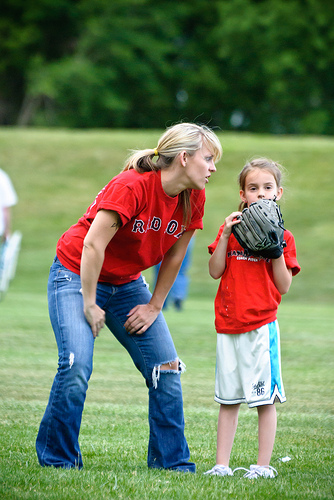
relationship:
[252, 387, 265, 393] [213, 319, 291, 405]
number on short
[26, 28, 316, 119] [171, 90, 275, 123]
branches in shade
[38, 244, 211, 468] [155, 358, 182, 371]
pants with tear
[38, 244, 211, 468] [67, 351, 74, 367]
pants with tear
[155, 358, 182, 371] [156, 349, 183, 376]
tear at knee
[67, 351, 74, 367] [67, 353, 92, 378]
tear at knee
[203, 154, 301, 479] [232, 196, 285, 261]
girl with glove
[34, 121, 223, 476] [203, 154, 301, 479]
woman giving advice to girl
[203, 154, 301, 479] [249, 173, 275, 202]
girl with look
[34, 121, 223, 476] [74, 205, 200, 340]
woman resting arms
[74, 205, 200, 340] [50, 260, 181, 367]
arms on thighs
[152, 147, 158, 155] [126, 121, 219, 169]
hairband in hair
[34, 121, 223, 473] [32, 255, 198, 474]
woman wearing pants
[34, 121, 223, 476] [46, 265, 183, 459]
woman wearing pants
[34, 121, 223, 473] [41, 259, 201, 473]
woman wearing jeans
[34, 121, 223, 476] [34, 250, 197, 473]
woman wearing pants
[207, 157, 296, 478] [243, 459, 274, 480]
girl wearing shoe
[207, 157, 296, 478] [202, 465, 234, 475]
girl wearing tennis shoe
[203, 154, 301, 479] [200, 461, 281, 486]
girl wearing shoes